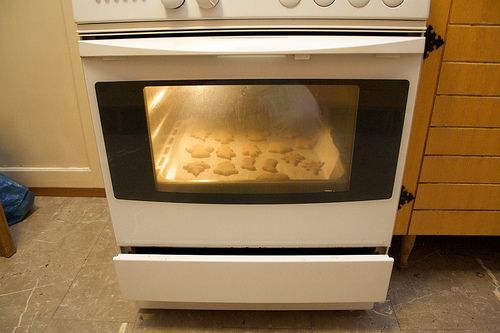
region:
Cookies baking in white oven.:
[70, 0, 430, 312]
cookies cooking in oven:
[120, 84, 356, 199]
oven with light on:
[140, 60, 370, 194]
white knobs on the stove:
[163, 0, 405, 20]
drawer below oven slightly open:
[106, 245, 400, 305]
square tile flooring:
[25, 189, 100, 326]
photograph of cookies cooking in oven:
[72, 0, 454, 307]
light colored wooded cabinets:
[399, 2, 499, 240]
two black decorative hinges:
[390, 18, 455, 211]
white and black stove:
[80, 0, 433, 315]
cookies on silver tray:
[155, 112, 349, 190]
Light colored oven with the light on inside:
[69, 2, 431, 314]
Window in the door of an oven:
[77, 40, 414, 205]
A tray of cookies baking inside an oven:
[155, 97, 349, 185]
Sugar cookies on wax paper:
[155, 104, 346, 185]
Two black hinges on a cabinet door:
[397, 12, 449, 222]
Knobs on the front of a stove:
[134, 1, 430, 18]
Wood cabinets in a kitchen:
[392, 2, 498, 265]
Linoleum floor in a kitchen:
[3, 182, 126, 329]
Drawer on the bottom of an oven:
[112, 252, 395, 315]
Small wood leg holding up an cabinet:
[395, 234, 417, 274]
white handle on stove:
[89, 35, 431, 58]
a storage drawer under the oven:
[114, 248, 397, 319]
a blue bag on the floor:
[0, 173, 38, 223]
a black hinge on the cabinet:
[427, 26, 444, 56]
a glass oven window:
[142, 82, 373, 199]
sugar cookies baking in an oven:
[181, 125, 328, 177]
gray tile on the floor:
[23, 219, 105, 328]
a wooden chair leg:
[3, 225, 20, 255]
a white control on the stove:
[154, 0, 187, 10]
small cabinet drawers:
[411, 60, 498, 237]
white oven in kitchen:
[92, 34, 430, 274]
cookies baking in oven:
[174, 110, 299, 185]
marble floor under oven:
[20, 255, 83, 320]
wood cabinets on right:
[455, 4, 498, 241]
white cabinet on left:
[0, 11, 66, 128]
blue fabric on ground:
[0, 171, 40, 228]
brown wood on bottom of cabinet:
[34, 175, 111, 207]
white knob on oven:
[169, 1, 171, 12]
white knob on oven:
[193, 0, 228, 17]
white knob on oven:
[280, 3, 290, 13]